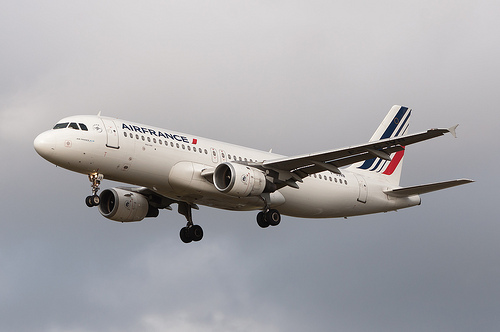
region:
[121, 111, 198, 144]
black letters on the side of a plane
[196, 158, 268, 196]
the left engine of a plane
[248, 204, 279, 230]
the left wheels of a plane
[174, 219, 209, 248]
the right wheels of a plane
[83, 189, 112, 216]
the front wheels of a plane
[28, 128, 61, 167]
the nose of a plane in the flying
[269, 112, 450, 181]
the left wing of a plane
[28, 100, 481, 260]
a plane flying in the air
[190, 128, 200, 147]
red paint on the side of black letters on a plane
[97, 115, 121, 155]
the door of a plane in the air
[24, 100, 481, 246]
Air france jumbo airliner jet plane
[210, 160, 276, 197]
left jet engine on airplane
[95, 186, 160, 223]
right jet engine on airplane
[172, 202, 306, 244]
Commercial jet landing gear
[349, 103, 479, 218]
Commercial jet tail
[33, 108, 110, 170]
Commercial Jet cockpit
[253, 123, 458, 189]
Left wing of commercial jet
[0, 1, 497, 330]
Commercial airliner flying after takeoff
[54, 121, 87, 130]
commercial jet windshield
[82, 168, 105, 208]
front wheel of commercial jet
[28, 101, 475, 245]
White plane in sky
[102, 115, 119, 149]
White door on white plane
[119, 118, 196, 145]
Logo on white plane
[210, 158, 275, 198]
White jet engine near wing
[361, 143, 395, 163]
Slat underneath large wing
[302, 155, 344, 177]
Slat underneath large wing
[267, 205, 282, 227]
Round black tire under wing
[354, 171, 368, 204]
Rear white door near tail of plane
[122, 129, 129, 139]
Small window underneath logo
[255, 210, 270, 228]
Round black tire next to round black tire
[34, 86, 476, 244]
A Air France jet in the sky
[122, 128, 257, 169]
The jets windows on the front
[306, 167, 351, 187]
The rear jet windows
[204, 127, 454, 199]
The jet's left wing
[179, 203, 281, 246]
The jet's rear wheels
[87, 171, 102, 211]
The front jet wheel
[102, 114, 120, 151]
The jet's locked front door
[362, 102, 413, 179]
The painted jet tail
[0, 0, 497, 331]
A jet flying in a gray sky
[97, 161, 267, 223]
The duo jet's double engines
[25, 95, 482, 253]
THE PLANE IS WHITE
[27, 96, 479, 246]
THE PLANE IS LANDING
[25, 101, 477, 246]
THE PLANE IS TAKING OFF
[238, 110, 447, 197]
THE PLANE'S WING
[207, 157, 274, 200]
THE PLANE'S ENGINE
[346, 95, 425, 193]
THE PLANE'S TAIL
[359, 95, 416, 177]
THE TAIL IS RED AND BLUE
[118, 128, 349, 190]
THE PLANE HAS MANY WINDOWS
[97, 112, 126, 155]
THE PLANE HAS A DOOR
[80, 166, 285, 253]
THE LANDING GEAR IS DOWN